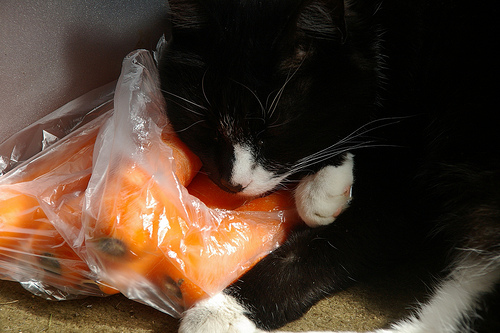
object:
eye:
[257, 110, 303, 130]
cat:
[151, 0, 499, 333]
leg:
[180, 216, 384, 331]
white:
[229, 142, 291, 196]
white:
[295, 152, 356, 228]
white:
[176, 291, 268, 333]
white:
[415, 291, 457, 331]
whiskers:
[283, 118, 401, 180]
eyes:
[170, 108, 209, 130]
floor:
[313, 291, 394, 333]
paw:
[295, 153, 354, 227]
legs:
[403, 180, 499, 332]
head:
[159, 0, 391, 196]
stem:
[97, 235, 132, 259]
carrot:
[0, 104, 292, 309]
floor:
[0, 280, 176, 333]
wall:
[0, 0, 170, 153]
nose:
[220, 172, 253, 193]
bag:
[0, 49, 303, 318]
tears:
[256, 137, 263, 144]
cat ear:
[159, 0, 207, 46]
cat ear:
[296, 0, 343, 39]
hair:
[259, 41, 344, 82]